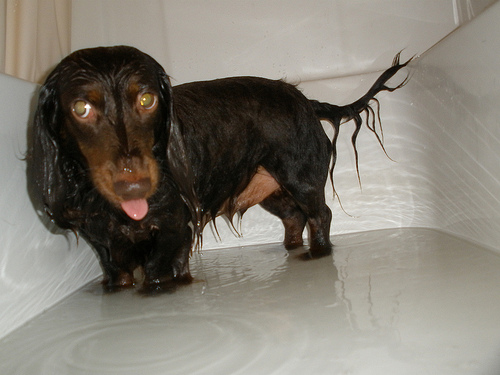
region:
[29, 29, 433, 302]
wet dog batheing in water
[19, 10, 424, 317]
dog taking a bath in water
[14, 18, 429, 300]
soaked dog in water looking at camera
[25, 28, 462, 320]
soaked dog in water sticking tongue out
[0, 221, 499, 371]
clouded water in a tube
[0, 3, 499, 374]
wet dog taking a bath in a tub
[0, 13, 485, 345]
dog soaked with water in a tub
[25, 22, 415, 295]
dog looking at camera during a bath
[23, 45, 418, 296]
small black dog taking a bath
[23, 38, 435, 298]
small black and brown dog in water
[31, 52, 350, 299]
the dog's hair is wet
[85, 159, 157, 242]
dog's tongue is sticking out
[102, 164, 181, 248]
dog's tongue is sticking out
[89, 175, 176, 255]
dog's tongue is sticking out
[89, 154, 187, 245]
dog's tongue is sticking out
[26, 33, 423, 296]
dog in the tub.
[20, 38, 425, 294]
Wet hair in the tub.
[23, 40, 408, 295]
Brown hair on the dog.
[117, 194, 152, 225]
Pink tongue on the dog.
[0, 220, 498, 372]
Water in the tub.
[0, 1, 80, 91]
Peach colored shower curtain.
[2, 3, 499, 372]
White tub in the forefront.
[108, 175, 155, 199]
Brown nose on the dog.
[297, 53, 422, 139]
Tail on the dog.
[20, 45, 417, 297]
a wet dog in a bathtub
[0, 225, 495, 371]
a pool of water in a bathtub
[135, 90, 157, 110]
the eye of a dog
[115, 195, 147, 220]
the pink tongue of a dog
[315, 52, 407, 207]
the wet straggly tail of a dog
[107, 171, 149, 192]
the brown nose of a dog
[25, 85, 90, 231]
the long wet ear of a dog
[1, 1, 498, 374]
a white bathtub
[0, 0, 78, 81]
a shower curtain on a bathtub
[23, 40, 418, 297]
Small wet brown dog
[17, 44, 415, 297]
Brown dog with green eyes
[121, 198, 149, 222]
Small pink dog tongue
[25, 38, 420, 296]
Dog taking a bath in a tub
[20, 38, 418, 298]
Wet dog sticking out his tongue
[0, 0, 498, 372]
White bathtub with water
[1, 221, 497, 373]
Shallow water in a bathtub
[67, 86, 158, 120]
Two green dog eyes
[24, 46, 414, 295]
Small brown dog with long ears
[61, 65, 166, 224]
Light brown dog face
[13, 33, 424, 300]
A wet small puppy.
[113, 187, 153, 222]
A pink tongue sticking out.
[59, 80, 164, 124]
Two greenish eyes on the puppy.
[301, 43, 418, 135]
The wet puppy's tail.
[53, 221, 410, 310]
Puppies paws in water.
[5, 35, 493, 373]
A white tub with water in it.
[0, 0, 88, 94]
Part of the shower curtain on the left.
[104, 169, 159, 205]
The brown nose of the puppy.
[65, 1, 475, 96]
The white back wall of the tub.